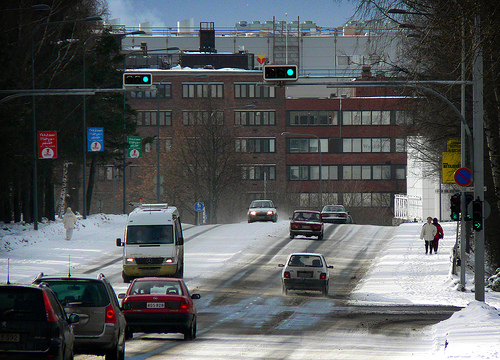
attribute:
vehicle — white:
[273, 244, 334, 296]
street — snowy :
[22, 194, 483, 348]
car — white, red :
[276, 248, 347, 290]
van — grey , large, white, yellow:
[113, 195, 197, 277]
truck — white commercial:
[114, 197, 200, 269]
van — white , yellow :
[118, 196, 192, 267]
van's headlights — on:
[119, 253, 179, 263]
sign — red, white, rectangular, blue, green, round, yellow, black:
[33, 131, 64, 161]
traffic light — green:
[117, 69, 163, 85]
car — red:
[115, 271, 207, 337]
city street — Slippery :
[30, 179, 463, 346]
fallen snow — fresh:
[369, 206, 420, 300]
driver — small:
[290, 252, 305, 266]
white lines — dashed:
[406, 229, 419, 270]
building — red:
[289, 95, 427, 221]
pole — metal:
[78, 106, 95, 206]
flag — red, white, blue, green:
[252, 50, 275, 73]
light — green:
[122, 71, 158, 84]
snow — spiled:
[447, 299, 492, 326]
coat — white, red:
[420, 220, 436, 239]